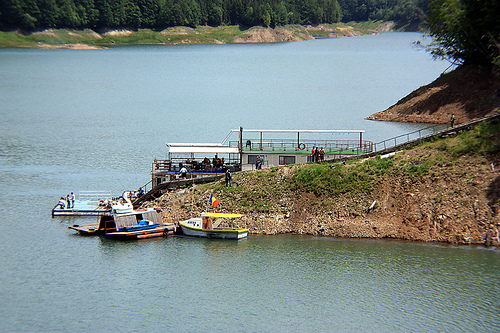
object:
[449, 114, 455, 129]
preserver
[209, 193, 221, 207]
flag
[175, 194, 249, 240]
boat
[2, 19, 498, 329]
water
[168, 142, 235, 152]
white roof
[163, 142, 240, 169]
structure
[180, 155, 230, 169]
people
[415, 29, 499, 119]
tree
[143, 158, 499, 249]
shoreline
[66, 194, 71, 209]
person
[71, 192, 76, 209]
person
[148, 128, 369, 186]
building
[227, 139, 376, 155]
rail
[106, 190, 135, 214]
boat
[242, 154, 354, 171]
wall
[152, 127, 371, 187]
building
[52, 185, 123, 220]
floating dock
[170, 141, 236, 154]
roof